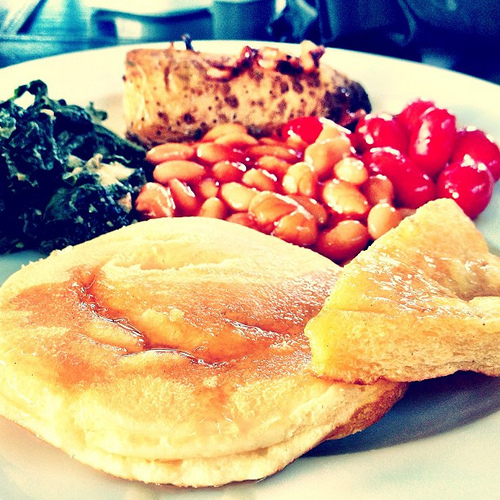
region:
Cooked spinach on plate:
[7, 81, 152, 267]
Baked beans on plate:
[138, 120, 397, 256]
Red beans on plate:
[358, 97, 497, 212]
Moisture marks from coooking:
[68, 267, 288, 377]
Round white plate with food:
[2, 39, 492, 499]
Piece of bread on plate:
[299, 197, 499, 386]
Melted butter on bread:
[358, 243, 497, 316]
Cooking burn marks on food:
[176, 33, 366, 115]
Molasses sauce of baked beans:
[167, 143, 287, 226]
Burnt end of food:
[327, 76, 371, 124]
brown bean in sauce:
[320, 179, 367, 216]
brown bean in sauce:
[370, 204, 399, 236]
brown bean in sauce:
[320, 224, 367, 256]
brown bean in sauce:
[277, 208, 319, 247]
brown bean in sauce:
[280, 162, 313, 197]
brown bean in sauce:
[303, 142, 330, 176]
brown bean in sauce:
[145, 141, 192, 162]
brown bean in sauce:
[152, 159, 203, 183]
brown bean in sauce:
[165, 177, 196, 212]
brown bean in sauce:
[217, 134, 257, 147]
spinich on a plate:
[0, 94, 115, 230]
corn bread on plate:
[311, 211, 498, 371]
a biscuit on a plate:
[0, 220, 336, 477]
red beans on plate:
[389, 104, 489, 197]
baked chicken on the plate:
[137, 51, 346, 124]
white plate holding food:
[9, 58, 496, 496]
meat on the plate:
[120, 57, 332, 135]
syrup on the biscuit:
[144, 328, 220, 382]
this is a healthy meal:
[46, 144, 351, 409]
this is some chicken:
[223, 34, 332, 195]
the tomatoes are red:
[419, 131, 496, 218]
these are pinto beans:
[264, 190, 299, 245]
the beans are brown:
[246, 154, 322, 261]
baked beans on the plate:
[144, 129, 399, 246]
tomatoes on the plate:
[379, 100, 497, 191]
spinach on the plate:
[16, 86, 132, 223]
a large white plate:
[3, 61, 491, 495]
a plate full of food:
[4, 37, 499, 497]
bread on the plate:
[26, 236, 350, 475]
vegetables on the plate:
[3, 82, 131, 239]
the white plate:
[358, 436, 484, 488]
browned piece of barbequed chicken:
[124, 41, 369, 148]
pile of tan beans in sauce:
[135, 112, 409, 259]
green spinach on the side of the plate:
[0, 76, 152, 256]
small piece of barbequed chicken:
[120, 41, 372, 146]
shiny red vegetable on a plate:
[355, 96, 499, 214]